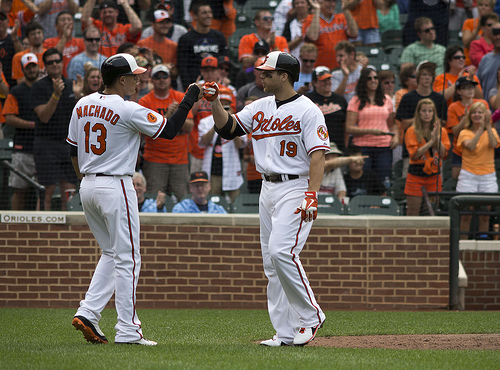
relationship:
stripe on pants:
[119, 178, 143, 341] [72, 179, 155, 344]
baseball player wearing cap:
[63, 52, 210, 347] [253, 49, 301, 84]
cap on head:
[253, 49, 301, 84] [100, 51, 147, 96]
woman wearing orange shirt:
[396, 90, 446, 215] [390, 127, 445, 192]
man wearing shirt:
[171, 171, 226, 212] [171, 197, 226, 213]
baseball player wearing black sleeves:
[60, 48, 225, 355] [126, 79, 202, 148]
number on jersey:
[80, 122, 122, 163] [64, 82, 172, 178]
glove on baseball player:
[299, 184, 318, 229] [201, 50, 331, 345]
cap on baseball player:
[253, 49, 301, 84] [218, 42, 345, 248]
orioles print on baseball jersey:
[245, 110, 304, 141] [231, 93, 330, 175]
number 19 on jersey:
[279, 138, 298, 158] [232, 94, 332, 177]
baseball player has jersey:
[201, 48, 331, 350] [232, 94, 332, 177]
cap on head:
[253, 49, 301, 84] [255, 50, 299, 92]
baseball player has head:
[201, 48, 331, 350] [255, 50, 299, 92]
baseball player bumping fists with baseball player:
[63, 52, 210, 347] [201, 50, 331, 345]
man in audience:
[171, 168, 229, 215] [2, 1, 499, 238]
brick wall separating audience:
[1, 214, 471, 316] [5, 3, 497, 194]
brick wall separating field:
[1, 214, 471, 316] [7, 300, 496, 368]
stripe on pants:
[119, 176, 147, 335] [71, 170, 143, 341]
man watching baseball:
[171, 168, 229, 215] [0, 50, 499, 369]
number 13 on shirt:
[81, 119, 106, 154] [65, 92, 166, 175]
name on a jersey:
[248, 109, 300, 132] [232, 94, 332, 177]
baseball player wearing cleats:
[201, 48, 331, 350] [260, 313, 326, 345]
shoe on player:
[69, 312, 109, 345] [62, 47, 187, 345]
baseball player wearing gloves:
[198, 48, 343, 348] [198, 80, 320, 222]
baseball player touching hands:
[201, 48, 331, 350] [186, 80, 218, 102]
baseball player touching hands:
[63, 52, 210, 347] [186, 80, 218, 102]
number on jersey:
[90, 122, 110, 157] [66, 90, 168, 176]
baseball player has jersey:
[63, 52, 210, 347] [66, 90, 168, 176]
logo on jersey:
[248, 115, 305, 142] [66, 90, 168, 176]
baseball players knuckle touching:
[184, 112, 214, 172] [61, 113, 327, 332]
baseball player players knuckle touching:
[63, 52, 210, 347] [61, 113, 327, 332]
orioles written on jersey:
[247, 118, 300, 160] [234, 89, 329, 184]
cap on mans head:
[253, 49, 304, 76] [226, 49, 325, 113]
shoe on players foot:
[68, 312, 112, 344] [113, 298, 174, 363]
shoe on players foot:
[257, 332, 295, 347] [232, 329, 333, 370]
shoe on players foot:
[247, 330, 291, 351] [259, 346, 292, 370]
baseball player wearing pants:
[63, 52, 210, 347] [72, 170, 149, 346]